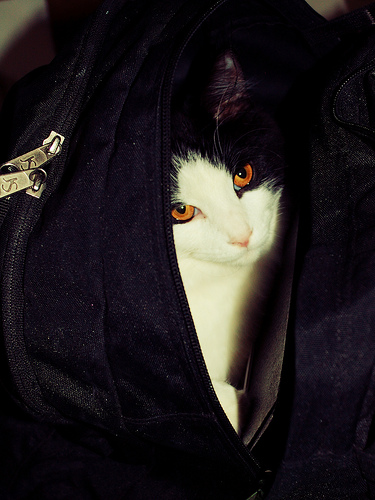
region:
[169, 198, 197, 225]
yellow eye of cat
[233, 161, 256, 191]
yellow eye of cat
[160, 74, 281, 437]
black and white cat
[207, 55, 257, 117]
black ear of a cat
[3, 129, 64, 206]
metal zipper of a purse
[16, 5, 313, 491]
cat in black bag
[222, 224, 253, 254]
pink nose of a cat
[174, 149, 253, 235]
white nose of a cat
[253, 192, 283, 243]
whiskers of a cat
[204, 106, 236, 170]
whiskers on top of cats head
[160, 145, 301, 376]
a cat in the bag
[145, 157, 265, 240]
cat's eyes are orange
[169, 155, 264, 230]
yellow -orange cat eyes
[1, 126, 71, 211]
metal zippers on luggaeg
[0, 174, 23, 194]
letters engraved on metal zipper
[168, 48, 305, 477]
black and white cat sitting in luggage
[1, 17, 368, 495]
black piece of luggage with cat inside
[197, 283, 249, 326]
patch of white fur on cat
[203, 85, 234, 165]
white whisker on cat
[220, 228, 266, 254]
pink cat nose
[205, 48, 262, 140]
inside of cat ear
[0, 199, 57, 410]
long curved texture of zipper